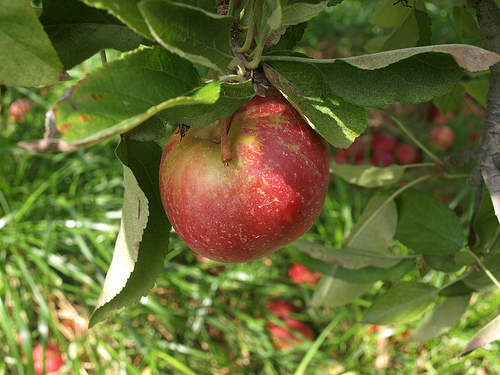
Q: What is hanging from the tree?
A: Apples.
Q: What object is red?
A: The apples.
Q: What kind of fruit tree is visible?
A: Apple tree.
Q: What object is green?
A: Leaves.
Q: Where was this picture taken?
A: In the garden.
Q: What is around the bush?
A: Some grass.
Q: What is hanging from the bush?
A: A stem.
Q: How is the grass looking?
A: Very green.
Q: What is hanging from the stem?
A: A apple.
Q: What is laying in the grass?
A: Apples.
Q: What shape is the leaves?
A: A oval shape.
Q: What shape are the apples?
A: All round.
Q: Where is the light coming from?
A: The sun.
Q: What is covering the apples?
A: The grass.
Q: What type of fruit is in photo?
A: Apple.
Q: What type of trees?
A: Apple trees.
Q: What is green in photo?
A: Leaves.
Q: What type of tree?
A: Fruit tree.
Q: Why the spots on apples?
A: Not ripe.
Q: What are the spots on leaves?
A: Dry spots.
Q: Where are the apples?
A: On the tree.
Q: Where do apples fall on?
A: Ground.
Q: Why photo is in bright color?
A: The sun.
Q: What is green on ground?
A: Grass.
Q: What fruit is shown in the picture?
A: Apple.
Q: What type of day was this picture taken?
A: A nice sunny day.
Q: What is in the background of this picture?
A: Leaves and apples.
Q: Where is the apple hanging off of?
A: A branch.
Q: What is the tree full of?
A: Apples.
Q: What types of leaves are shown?
A: Green leaves.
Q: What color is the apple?
A: Red.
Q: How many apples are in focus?
A: One.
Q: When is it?
A: Day time.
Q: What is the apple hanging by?
A: A stem.